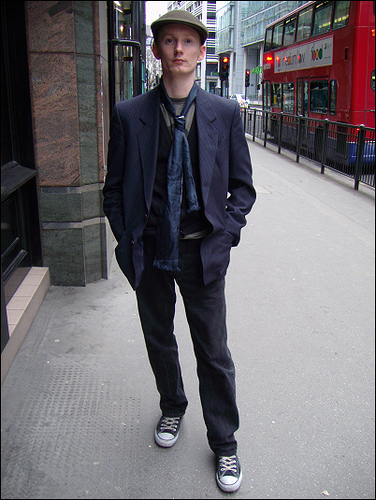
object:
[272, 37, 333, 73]
lettering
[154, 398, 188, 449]
foot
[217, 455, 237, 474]
shoe laces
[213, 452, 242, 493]
sneaker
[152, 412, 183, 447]
sneaker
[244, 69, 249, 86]
traffic light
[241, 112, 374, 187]
street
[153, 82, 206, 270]
scarf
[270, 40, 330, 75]
advertisement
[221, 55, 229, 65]
light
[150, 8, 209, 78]
head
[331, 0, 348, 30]
windows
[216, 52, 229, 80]
traffic lights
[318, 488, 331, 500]
spot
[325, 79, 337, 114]
window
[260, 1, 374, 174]
bus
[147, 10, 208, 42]
green cap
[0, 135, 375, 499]
sidewalk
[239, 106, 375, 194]
railing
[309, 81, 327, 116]
windows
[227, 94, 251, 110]
vehicle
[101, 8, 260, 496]
man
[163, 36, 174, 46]
eye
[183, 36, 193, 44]
eye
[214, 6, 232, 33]
windows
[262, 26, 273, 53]
windows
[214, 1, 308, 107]
building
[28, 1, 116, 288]
side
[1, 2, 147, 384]
building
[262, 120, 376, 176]
blue bottom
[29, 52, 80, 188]
block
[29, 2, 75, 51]
block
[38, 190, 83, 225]
block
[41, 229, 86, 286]
block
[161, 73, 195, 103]
neck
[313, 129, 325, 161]
tire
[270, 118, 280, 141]
tire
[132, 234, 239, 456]
pants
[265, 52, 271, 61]
light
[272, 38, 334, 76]
imaging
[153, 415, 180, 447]
right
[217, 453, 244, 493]
left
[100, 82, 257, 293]
jacket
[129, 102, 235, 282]
front